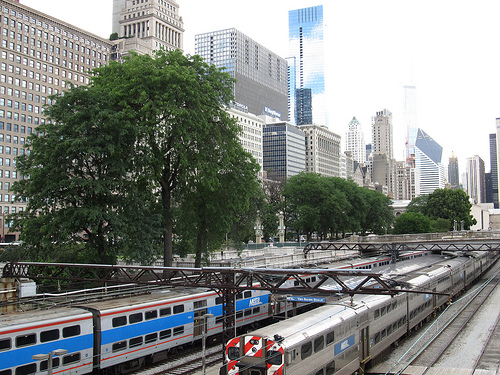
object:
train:
[226, 248, 500, 374]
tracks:
[393, 261, 500, 375]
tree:
[0, 48, 262, 285]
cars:
[0, 299, 93, 374]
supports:
[2, 260, 453, 297]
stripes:
[225, 334, 242, 354]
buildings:
[0, 0, 121, 243]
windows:
[42, 63, 47, 72]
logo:
[248, 296, 264, 307]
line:
[97, 291, 215, 317]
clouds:
[418, 22, 481, 54]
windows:
[128, 312, 143, 324]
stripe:
[99, 291, 217, 318]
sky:
[18, 0, 500, 175]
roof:
[414, 126, 443, 167]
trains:
[0, 247, 458, 375]